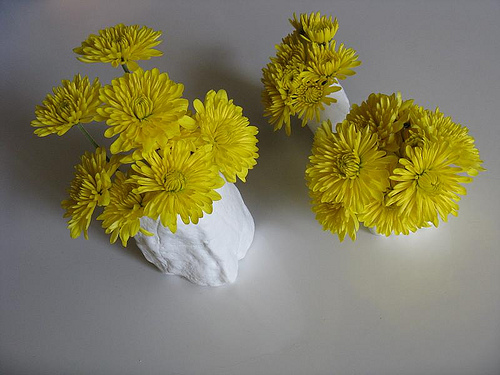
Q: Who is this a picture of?
A: No one.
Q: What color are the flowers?
A: Yellow.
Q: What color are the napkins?
A: White.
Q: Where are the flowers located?
A: On a table.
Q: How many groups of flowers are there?
A: Three.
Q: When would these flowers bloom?
A: Spring.